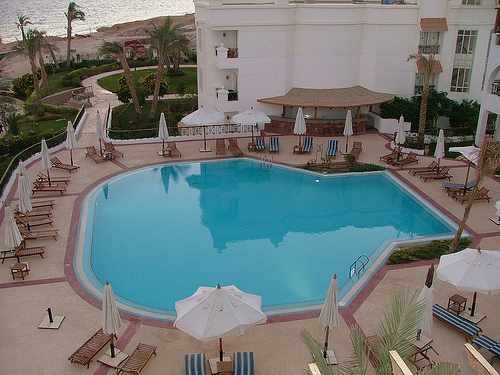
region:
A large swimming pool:
[76, 148, 461, 324]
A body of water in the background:
[1, 2, 198, 47]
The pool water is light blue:
[68, 150, 480, 317]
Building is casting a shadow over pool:
[184, 153, 438, 261]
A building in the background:
[178, 0, 498, 141]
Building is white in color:
[176, 1, 498, 172]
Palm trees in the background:
[11, 0, 186, 130]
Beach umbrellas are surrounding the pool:
[0, 105, 496, 361]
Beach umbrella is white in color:
[167, 270, 277, 365]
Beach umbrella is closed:
[81, 270, 135, 350]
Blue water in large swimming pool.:
[82, 192, 375, 264]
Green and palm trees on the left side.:
[102, 29, 189, 114]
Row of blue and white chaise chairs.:
[247, 133, 341, 156]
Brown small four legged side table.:
[447, 284, 479, 315]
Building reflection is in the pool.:
[140, 191, 390, 253]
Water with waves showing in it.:
[16, 3, 131, 15]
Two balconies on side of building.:
[210, 23, 242, 117]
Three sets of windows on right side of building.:
[444, 0, 490, 102]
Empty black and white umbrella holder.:
[37, 298, 67, 338]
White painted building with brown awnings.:
[254, 13, 450, 85]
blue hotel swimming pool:
[72, 148, 461, 330]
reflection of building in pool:
[197, 167, 412, 240]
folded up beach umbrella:
[100, 273, 128, 363]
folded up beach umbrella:
[36, 140, 59, 186]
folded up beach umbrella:
[89, 110, 111, 149]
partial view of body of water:
[0, 2, 201, 35]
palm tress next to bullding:
[103, 15, 190, 116]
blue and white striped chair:
[322, 135, 342, 169]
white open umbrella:
[171, 273, 274, 373]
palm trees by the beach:
[4, 5, 71, 124]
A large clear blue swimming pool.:
[78, 156, 461, 322]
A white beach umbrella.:
[176, 283, 266, 342]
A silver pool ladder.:
[351, 252, 374, 275]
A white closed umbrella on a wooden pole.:
[320, 274, 340, 356]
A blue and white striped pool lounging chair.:
[425, 297, 480, 341]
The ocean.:
[2, 1, 196, 49]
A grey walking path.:
[75, 63, 200, 150]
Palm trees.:
[14, 4, 182, 128]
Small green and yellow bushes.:
[12, 72, 169, 107]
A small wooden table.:
[445, 292, 467, 314]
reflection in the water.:
[241, 188, 286, 216]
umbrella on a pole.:
[188, 290, 244, 322]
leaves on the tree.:
[385, 305, 409, 348]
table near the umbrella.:
[11, 262, 26, 281]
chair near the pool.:
[140, 340, 150, 372]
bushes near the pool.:
[396, 242, 438, 261]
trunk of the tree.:
[453, 189, 478, 243]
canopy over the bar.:
[280, 84, 374, 110]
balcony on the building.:
[213, 40, 235, 61]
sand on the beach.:
[78, 31, 100, 48]